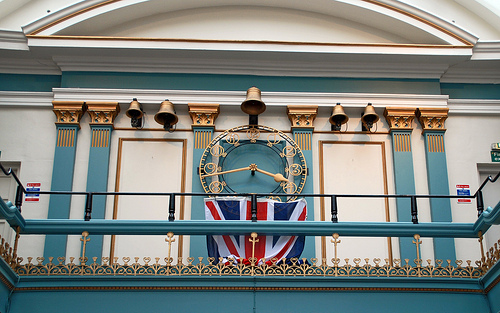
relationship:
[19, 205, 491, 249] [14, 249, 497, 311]
railing on balcony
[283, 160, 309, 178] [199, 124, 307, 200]
number 3 on clock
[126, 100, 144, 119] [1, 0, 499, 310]
light on building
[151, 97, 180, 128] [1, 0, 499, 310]
light on building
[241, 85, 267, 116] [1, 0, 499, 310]
light on building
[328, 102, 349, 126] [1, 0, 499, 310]
light on building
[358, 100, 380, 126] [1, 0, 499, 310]
light on building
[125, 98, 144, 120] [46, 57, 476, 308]
bell on wall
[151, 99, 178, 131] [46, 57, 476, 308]
bell on wall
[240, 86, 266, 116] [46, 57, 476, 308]
bell on wall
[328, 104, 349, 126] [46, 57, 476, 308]
bell on wall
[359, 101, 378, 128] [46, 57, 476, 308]
bell on wall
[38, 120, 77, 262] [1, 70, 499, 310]
pillar on wall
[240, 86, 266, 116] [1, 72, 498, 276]
bell on wall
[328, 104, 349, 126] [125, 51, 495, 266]
bell on wall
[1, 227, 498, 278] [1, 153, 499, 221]
decorative pattern underneath railing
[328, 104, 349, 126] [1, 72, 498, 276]
bell on wall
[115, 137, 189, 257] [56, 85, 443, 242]
decal on wall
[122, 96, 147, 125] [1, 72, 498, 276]
bell on wall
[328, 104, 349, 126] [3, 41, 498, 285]
bell on wall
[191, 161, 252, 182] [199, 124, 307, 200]
hand on clock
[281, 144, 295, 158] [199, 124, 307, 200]
2 on clock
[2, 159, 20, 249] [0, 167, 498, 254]
doorway behind railing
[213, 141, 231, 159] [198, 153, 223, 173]
9 in metal-work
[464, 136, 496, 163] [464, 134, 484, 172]
sign with lettering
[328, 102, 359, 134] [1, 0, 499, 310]
light on building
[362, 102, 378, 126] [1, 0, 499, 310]
light on building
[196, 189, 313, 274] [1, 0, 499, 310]
flag on building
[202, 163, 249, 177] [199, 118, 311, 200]
hand of clock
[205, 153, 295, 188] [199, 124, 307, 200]
time on clock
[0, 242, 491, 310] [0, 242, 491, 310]
area overlooking an area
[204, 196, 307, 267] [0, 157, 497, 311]
flag hanging from a balcony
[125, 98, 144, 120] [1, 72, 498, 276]
bell on wall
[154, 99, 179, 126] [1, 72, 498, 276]
bell on wall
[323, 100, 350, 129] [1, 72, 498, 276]
bell on wall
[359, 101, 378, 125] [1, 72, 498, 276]
bell on wall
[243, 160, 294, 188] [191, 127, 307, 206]
hour hand of clock